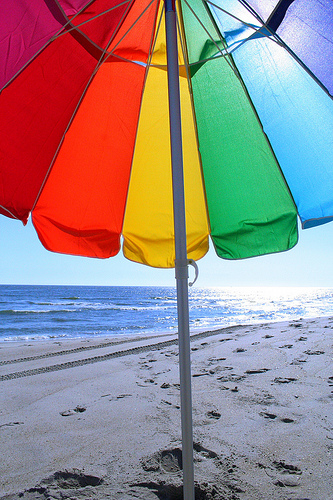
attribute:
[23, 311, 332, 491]
beach — part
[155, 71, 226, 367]
pole — silver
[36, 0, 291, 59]
braces — connecting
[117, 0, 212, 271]
cloth — yellow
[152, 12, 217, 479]
post — part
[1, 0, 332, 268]
ubrella — green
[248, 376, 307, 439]
sand — wet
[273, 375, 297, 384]
footprint — man's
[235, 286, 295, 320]
sun reflection — reflecting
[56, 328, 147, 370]
tracks — vehicle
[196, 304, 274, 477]
tracks — people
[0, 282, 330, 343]
water — large body, blue, ocean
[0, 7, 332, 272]
umbrella — rainbow, multi-colored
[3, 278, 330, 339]
water — sparkling, reflecting